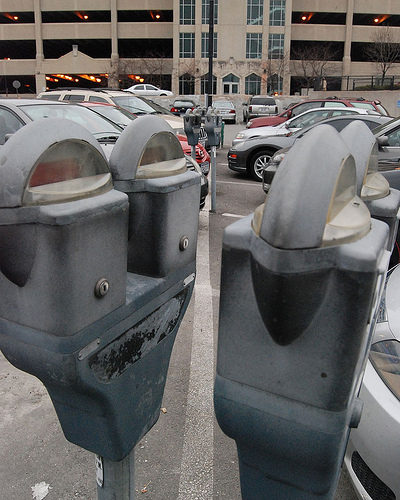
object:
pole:
[93, 454, 134, 498]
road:
[134, 212, 239, 498]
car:
[227, 114, 394, 183]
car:
[123, 83, 173, 96]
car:
[35, 88, 207, 141]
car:
[78, 102, 210, 175]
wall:
[217, 2, 244, 58]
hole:
[94, 277, 109, 298]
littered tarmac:
[213, 124, 389, 499]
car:
[231, 108, 381, 144]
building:
[0, 2, 399, 94]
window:
[246, 32, 262, 59]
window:
[201, 33, 218, 58]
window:
[268, 33, 284, 60]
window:
[179, 32, 196, 58]